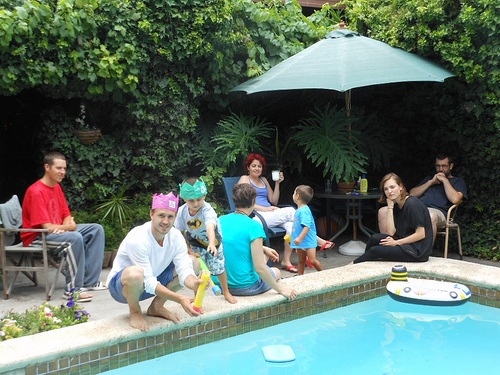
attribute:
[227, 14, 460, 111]
umbrella — green, open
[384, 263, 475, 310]
floaty — white, black, round, inflatable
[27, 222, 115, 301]
pants — gray, white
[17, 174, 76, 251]
shirt — red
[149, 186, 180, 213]
crown — pink, teal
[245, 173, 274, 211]
tank top — blue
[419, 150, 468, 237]
man — sitting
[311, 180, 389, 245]
table — glass, metal, round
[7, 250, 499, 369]
swimming pool — here, blue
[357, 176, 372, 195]
cup — yellow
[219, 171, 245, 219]
patio chair — blue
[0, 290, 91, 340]
garden — here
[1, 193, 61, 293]
chair — metal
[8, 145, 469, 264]
people — sitting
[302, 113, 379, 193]
plant — green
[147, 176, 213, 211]
crowns — here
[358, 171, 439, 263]
person — aloof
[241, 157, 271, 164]
hair — red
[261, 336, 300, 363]
board — foam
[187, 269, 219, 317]
squirt guns — here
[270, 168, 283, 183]
mug — white